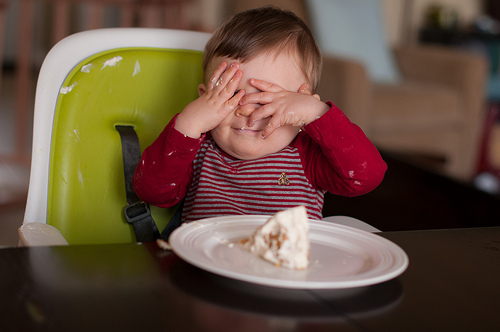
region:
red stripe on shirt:
[198, 148, 218, 155]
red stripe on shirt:
[196, 151, 223, 163]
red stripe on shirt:
[200, 163, 305, 183]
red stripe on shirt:
[243, 155, 300, 167]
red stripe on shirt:
[280, 147, 299, 152]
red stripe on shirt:
[191, 207, 236, 220]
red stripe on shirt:
[191, 201, 238, 214]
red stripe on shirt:
[195, 189, 284, 209]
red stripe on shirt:
[303, 203, 321, 219]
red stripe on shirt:
[307, 202, 322, 214]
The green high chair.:
[33, 30, 231, 245]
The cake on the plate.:
[248, 212, 318, 266]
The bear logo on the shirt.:
[273, 175, 289, 186]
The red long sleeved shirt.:
[135, 118, 384, 229]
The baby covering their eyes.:
[125, 7, 388, 218]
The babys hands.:
[200, 63, 322, 135]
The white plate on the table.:
[165, 214, 411, 298]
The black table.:
[7, 248, 179, 325]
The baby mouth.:
[231, 121, 276, 139]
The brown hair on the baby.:
[202, 6, 332, 75]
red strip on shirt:
[279, 147, 298, 154]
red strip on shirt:
[263, 152, 302, 161]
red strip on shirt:
[201, 138, 213, 145]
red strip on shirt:
[251, 156, 300, 165]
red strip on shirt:
[236, 168, 301, 175]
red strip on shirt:
[238, 178, 278, 188]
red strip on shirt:
[286, 168, 303, 173]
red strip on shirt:
[288, 173, 304, 183]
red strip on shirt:
[291, 178, 310, 187]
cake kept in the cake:
[241, 202, 323, 269]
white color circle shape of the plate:
[165, 193, 428, 299]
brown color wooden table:
[41, 226, 494, 321]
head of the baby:
[182, 8, 341, 158]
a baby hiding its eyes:
[193, 70, 327, 159]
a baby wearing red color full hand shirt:
[142, 107, 370, 210]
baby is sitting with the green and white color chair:
[11, 2, 347, 277]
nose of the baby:
[232, 98, 267, 124]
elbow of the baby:
[336, 131, 398, 205]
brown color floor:
[404, 168, 447, 218]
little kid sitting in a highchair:
[30, 12, 422, 255]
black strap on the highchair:
[113, 127, 174, 248]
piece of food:
[235, 191, 322, 279]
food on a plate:
[160, 195, 420, 300]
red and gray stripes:
[184, 143, 325, 227]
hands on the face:
[181, 44, 326, 163]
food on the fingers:
[209, 71, 227, 91]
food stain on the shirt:
[346, 158, 372, 189]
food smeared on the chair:
[47, 47, 152, 109]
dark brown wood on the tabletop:
[3, 224, 498, 328]